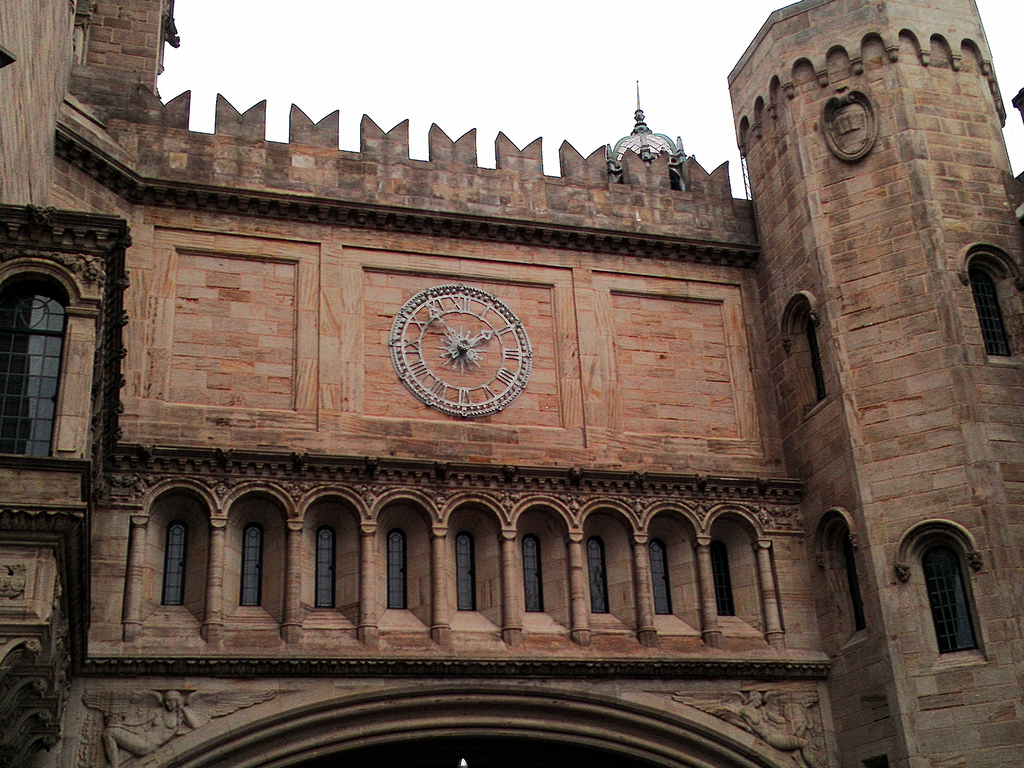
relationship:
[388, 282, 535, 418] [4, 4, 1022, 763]
clock on building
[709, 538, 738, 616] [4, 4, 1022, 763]
window on building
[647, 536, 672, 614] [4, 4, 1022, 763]
window on building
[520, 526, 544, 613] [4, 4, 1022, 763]
window on building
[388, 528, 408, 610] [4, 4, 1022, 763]
window on building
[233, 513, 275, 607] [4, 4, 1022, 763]
window on building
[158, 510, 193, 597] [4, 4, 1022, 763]
window on building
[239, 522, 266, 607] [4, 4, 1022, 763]
window on building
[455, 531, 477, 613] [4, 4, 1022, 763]
window on building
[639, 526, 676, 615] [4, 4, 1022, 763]
window on building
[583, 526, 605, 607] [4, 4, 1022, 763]
window on building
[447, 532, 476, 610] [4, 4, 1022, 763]
window on building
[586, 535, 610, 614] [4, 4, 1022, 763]
window on building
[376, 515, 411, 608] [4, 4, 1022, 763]
window on building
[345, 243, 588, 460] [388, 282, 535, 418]
design behind clock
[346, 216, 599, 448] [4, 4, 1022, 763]
clock on a building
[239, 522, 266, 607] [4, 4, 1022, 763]
window in building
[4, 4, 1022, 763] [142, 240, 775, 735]
building has wall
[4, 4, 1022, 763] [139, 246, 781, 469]
building has wall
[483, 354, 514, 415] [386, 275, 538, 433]
roman numeralas on clock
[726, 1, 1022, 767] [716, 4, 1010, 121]
tower has top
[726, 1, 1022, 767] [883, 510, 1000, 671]
tower has window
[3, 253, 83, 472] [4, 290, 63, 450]
window has dividers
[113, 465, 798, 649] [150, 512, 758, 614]
pillars inlaid along a row of windows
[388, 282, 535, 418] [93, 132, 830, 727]
clock fastened to a wall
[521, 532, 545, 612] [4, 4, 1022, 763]
window in a building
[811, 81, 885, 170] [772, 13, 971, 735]
crest on a wall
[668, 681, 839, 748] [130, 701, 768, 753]
angel sitting above an archway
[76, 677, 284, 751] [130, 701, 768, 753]
angel sitting above an archway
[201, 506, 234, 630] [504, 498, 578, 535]
pillars and arches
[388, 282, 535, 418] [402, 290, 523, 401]
clock displaying numerals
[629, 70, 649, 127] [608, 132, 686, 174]
spire on a roof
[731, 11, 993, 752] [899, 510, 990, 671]
tower with windows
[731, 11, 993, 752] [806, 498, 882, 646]
tower with windows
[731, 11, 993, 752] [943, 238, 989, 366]
tower with windows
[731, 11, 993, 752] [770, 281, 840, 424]
tower with windows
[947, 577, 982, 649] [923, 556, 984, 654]
reflection in a pane